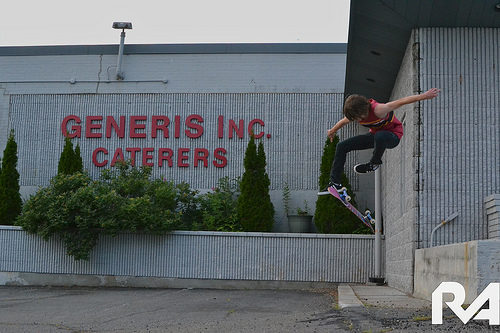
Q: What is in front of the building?
A: The tree is in front of the building.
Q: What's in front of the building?
A: The tree is in front of the building.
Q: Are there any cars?
A: No, there are no cars.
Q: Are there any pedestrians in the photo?
A: No, there are no pedestrians.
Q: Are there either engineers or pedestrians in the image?
A: No, there are no pedestrians or engineers.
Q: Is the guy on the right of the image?
A: Yes, the guy is on the right of the image.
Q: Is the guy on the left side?
A: No, the guy is on the right of the image.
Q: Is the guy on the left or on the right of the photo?
A: The guy is on the right of the image.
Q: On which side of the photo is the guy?
A: The guy is on the right of the image.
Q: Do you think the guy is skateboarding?
A: Yes, the guy is skateboarding.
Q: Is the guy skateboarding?
A: Yes, the guy is skateboarding.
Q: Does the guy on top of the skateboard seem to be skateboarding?
A: Yes, the guy is skateboarding.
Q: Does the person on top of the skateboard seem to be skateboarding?
A: Yes, the guy is skateboarding.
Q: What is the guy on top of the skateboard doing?
A: The guy is skateboarding.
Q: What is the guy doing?
A: The guy is skateboarding.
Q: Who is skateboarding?
A: The guy is skateboarding.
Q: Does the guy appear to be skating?
A: No, the guy is skateboarding.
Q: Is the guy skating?
A: No, the guy is skateboarding.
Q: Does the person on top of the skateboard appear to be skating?
A: No, the guy is skateboarding.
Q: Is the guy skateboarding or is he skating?
A: The guy is skateboarding.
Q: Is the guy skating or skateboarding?
A: The guy is skateboarding.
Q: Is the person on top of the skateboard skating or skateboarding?
A: The guy is skateboarding.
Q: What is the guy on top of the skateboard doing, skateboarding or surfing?
A: The guy is skateboarding.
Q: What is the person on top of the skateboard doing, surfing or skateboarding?
A: The guy is skateboarding.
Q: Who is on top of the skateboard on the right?
A: The guy is on top of the skateboard.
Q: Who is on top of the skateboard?
A: The guy is on top of the skateboard.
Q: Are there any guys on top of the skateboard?
A: Yes, there is a guy on top of the skateboard.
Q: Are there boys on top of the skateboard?
A: No, there is a guy on top of the skateboard.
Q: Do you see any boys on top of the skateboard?
A: No, there is a guy on top of the skateboard.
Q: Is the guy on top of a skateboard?
A: Yes, the guy is on top of a skateboard.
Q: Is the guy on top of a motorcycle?
A: No, the guy is on top of a skateboard.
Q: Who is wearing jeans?
A: The guy is wearing jeans.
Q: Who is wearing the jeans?
A: The guy is wearing jeans.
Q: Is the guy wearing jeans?
A: Yes, the guy is wearing jeans.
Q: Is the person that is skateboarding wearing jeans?
A: Yes, the guy is wearing jeans.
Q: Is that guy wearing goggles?
A: No, the guy is wearing jeans.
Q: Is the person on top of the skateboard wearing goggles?
A: No, the guy is wearing jeans.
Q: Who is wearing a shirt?
A: The guy is wearing a shirt.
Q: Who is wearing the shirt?
A: The guy is wearing a shirt.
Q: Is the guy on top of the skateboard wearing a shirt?
A: Yes, the guy is wearing a shirt.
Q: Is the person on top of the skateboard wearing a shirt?
A: Yes, the guy is wearing a shirt.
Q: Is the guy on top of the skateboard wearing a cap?
A: No, the guy is wearing a shirt.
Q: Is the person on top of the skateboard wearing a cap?
A: No, the guy is wearing a shirt.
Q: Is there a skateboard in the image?
A: Yes, there is a skateboard.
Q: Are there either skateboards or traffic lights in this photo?
A: Yes, there is a skateboard.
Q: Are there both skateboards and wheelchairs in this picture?
A: No, there is a skateboard but no wheelchairs.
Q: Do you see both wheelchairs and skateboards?
A: No, there is a skateboard but no wheelchairs.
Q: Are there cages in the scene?
A: No, there are no cages.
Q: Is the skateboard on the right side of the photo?
A: Yes, the skateboard is on the right of the image.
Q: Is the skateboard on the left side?
A: No, the skateboard is on the right of the image.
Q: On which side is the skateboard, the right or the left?
A: The skateboard is on the right of the image.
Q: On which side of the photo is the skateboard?
A: The skateboard is on the right of the image.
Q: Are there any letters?
A: Yes, there are letters.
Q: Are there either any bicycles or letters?
A: Yes, there are letters.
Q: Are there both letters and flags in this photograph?
A: No, there are letters but no flags.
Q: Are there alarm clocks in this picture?
A: No, there are no alarm clocks.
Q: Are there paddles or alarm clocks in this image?
A: No, there are no alarm clocks or paddles.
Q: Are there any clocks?
A: No, there are no clocks.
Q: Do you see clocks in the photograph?
A: No, there are no clocks.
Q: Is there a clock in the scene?
A: No, there are no clocks.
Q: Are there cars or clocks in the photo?
A: No, there are no clocks or cars.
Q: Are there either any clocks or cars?
A: No, there are no clocks or cars.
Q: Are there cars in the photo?
A: No, there are no cars.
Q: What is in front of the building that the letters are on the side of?
A: The tree is in front of the building.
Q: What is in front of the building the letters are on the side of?
A: The tree is in front of the building.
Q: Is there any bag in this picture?
A: No, there are no bags.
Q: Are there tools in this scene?
A: No, there are no tools.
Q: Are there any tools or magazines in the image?
A: No, there are no tools or magazines.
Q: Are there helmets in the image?
A: No, there are no helmets.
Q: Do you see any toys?
A: No, there are no toys.